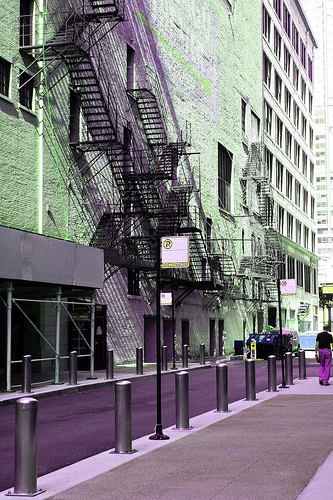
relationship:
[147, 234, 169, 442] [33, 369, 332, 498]
pole on sidewalk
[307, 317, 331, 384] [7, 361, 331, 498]
man on sidewalk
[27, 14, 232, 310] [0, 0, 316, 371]
ladders on building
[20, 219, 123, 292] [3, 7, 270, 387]
awning over storefront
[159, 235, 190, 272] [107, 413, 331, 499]
sign on sidewalk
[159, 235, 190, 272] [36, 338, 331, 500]
sign on sidewalk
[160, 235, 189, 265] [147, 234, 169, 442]
sign on pole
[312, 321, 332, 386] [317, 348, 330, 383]
man wearing pants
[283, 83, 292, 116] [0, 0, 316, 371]
window on building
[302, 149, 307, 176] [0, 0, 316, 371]
window on building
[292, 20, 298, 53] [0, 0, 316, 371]
window on building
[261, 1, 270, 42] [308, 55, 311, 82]
window on window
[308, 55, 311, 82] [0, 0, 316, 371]
window on building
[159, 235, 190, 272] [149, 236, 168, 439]
sign on pole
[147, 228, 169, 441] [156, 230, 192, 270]
pole with sign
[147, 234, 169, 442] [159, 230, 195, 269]
pole with sign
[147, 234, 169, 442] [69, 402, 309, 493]
pole on sidewalk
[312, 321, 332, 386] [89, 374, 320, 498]
man walking sidewalk